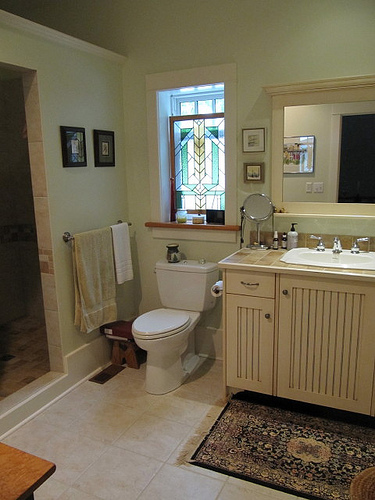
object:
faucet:
[351, 236, 370, 254]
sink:
[280, 247, 375, 271]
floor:
[0, 354, 375, 500]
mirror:
[241, 192, 274, 251]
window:
[169, 113, 225, 222]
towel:
[71, 228, 119, 336]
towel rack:
[62, 231, 76, 243]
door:
[275, 273, 374, 415]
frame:
[93, 130, 116, 168]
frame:
[60, 127, 88, 169]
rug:
[188, 391, 375, 500]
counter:
[217, 241, 375, 416]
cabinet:
[277, 274, 375, 415]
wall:
[0, 12, 132, 375]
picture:
[59, 126, 87, 167]